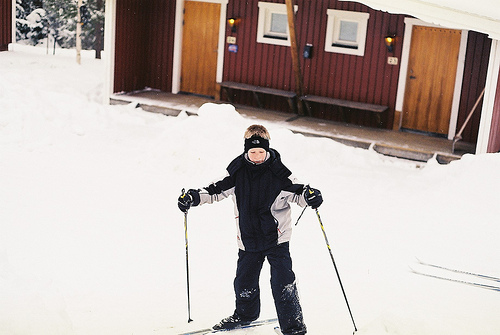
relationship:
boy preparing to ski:
[178, 121, 327, 334] [311, 194, 365, 334]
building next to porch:
[106, 0, 499, 165] [110, 82, 480, 168]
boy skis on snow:
[178, 121, 327, 334] [2, 55, 498, 335]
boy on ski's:
[178, 121, 327, 333] [151, 122, 414, 331]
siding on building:
[224, 3, 404, 108] [199, 0, 376, 92]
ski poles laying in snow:
[404, 242, 488, 297] [2, 55, 498, 335]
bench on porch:
[298, 92, 388, 126] [111, 68, 479, 171]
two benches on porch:
[220, 79, 388, 128] [111, 68, 479, 171]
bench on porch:
[218, 79, 297, 111] [111, 68, 479, 171]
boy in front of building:
[178, 121, 327, 333] [106, 0, 499, 165]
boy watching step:
[178, 121, 327, 333] [203, 318, 315, 333]